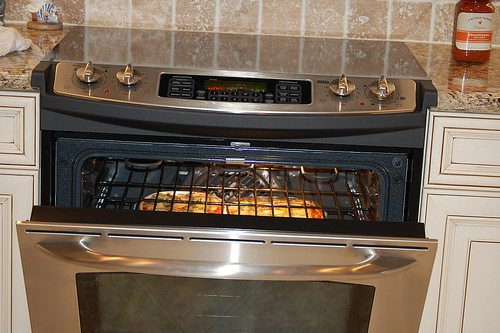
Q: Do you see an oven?
A: Yes, there is an oven.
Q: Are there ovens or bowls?
A: Yes, there is an oven.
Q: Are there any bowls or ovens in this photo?
A: Yes, there is an oven.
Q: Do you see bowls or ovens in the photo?
A: Yes, there is an oven.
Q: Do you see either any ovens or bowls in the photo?
A: Yes, there is an oven.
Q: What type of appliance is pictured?
A: The appliance is an oven.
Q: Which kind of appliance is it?
A: The appliance is an oven.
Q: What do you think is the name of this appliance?
A: This is an oven.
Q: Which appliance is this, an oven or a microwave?
A: This is an oven.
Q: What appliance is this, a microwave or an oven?
A: This is an oven.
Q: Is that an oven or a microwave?
A: That is an oven.